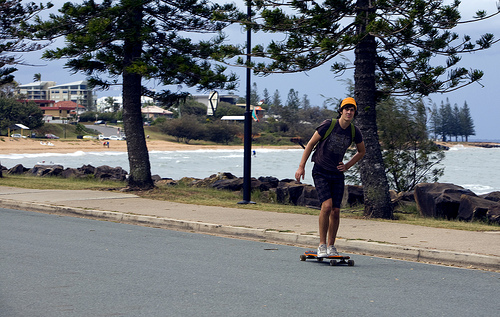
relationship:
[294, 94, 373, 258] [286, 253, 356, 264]
man on skateboard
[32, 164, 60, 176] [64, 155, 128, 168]
rocks near water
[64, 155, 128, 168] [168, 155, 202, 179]
water in background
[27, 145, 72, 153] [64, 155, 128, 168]
beach by water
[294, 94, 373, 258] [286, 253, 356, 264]
man on top skateboard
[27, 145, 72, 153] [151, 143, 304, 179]
beach next to ocean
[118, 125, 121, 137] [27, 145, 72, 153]
person on beach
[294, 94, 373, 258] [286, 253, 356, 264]
man on top of skateboard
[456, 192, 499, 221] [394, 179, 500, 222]
rock along shoreline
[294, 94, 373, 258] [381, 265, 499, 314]
skateboarder on top of pavement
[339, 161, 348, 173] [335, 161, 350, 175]
hand on top of hip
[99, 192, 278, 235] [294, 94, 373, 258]
sidewalk next skateboarder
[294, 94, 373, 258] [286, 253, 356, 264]
man riding skateboard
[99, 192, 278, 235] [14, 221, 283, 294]
sidewalk along road